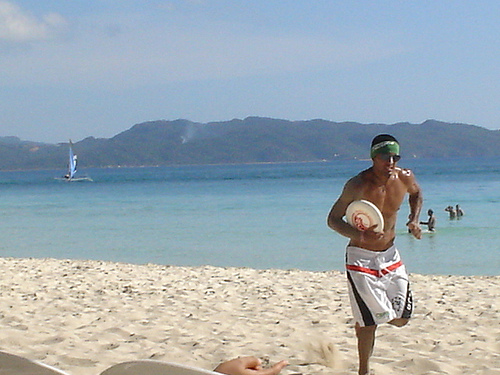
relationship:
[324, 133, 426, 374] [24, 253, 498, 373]
man running on beach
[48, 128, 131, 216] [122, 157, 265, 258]
sail boat in water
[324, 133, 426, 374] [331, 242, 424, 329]
man wearing shorts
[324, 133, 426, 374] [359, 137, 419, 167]
man wearing head band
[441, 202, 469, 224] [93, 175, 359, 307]
person in water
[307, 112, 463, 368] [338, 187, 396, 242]
man with frisbee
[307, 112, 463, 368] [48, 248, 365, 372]
man running on beach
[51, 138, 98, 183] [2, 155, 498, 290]
sail boat in water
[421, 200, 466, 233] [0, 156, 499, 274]
people in water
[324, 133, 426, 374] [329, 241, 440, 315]
man wearing trunks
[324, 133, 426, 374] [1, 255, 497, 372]
man running in sand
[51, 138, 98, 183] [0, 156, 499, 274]
sail boat in water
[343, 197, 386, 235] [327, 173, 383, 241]
frisbee in arm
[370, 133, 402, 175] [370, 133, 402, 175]
head on head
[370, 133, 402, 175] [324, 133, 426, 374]
head on man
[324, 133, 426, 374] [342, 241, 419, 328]
man wearing shorts